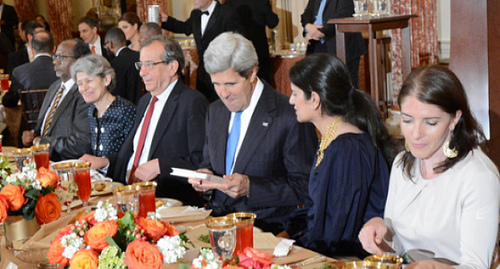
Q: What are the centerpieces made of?
A: Flowers.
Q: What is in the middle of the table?
A: Pink flowers.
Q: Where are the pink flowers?
A: Centerpieces.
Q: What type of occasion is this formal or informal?
A: Formal.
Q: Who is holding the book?
A: The man with the blue tie.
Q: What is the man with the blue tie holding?
A: A book.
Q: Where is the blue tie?
A: On the man with the book.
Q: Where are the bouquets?
A: On the table.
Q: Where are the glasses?
A: Behind the bouquets.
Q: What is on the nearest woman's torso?
A: A white blouse.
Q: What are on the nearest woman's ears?
A: Earrings.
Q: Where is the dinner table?
A: In front of the people.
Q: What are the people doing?
A: Sitting.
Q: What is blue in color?
A: A tie.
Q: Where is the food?
A: On the table.